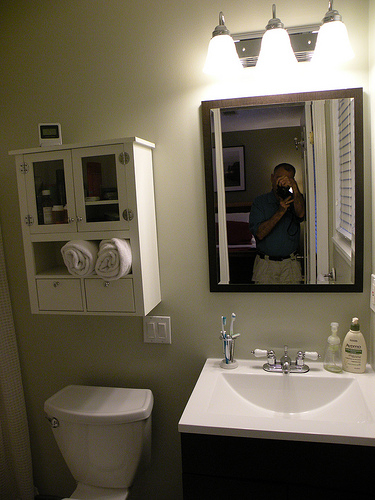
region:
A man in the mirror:
[248, 166, 304, 284]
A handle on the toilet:
[45, 416, 57, 425]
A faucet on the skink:
[254, 342, 318, 374]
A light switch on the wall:
[145, 316, 170, 341]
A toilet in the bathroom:
[45, 370, 152, 498]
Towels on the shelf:
[62, 237, 131, 275]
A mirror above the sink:
[208, 98, 355, 288]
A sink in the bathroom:
[222, 346, 353, 418]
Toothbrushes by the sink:
[218, 311, 238, 360]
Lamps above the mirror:
[208, 13, 350, 65]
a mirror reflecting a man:
[200, 88, 362, 290]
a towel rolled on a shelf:
[95, 237, 132, 282]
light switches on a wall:
[142, 313, 169, 346]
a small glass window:
[80, 155, 121, 223]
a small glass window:
[32, 157, 70, 225]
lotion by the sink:
[342, 316, 366, 372]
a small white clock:
[39, 121, 62, 146]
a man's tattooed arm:
[257, 196, 291, 240]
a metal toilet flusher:
[44, 413, 59, 428]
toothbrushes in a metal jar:
[218, 312, 239, 368]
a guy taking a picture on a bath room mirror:
[244, 148, 312, 292]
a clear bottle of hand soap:
[324, 310, 344, 378]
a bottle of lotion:
[341, 315, 367, 377]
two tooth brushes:
[214, 302, 249, 338]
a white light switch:
[139, 314, 175, 346]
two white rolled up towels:
[56, 234, 142, 283]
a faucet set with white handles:
[250, 337, 319, 378]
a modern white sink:
[176, 332, 373, 465]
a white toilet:
[32, 373, 146, 499]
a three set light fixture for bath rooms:
[193, 7, 369, 82]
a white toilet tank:
[43, 382, 154, 487]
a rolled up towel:
[92, 237, 132, 279]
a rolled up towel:
[59, 240, 97, 275]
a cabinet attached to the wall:
[9, 136, 162, 315]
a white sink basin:
[220, 369, 353, 412]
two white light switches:
[141, 316, 172, 342]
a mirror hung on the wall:
[199, 87, 365, 291]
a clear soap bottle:
[321, 319, 345, 373]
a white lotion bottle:
[339, 316, 366, 372]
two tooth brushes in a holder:
[218, 309, 237, 363]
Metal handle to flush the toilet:
[42, 411, 58, 429]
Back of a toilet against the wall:
[41, 379, 154, 488]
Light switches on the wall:
[140, 314, 171, 346]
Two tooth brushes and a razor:
[220, 311, 240, 368]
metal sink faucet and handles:
[249, 342, 319, 378]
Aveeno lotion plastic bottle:
[340, 315, 367, 373]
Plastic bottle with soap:
[320, 317, 345, 373]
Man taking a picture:
[248, 160, 309, 283]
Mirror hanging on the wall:
[193, 85, 368, 292]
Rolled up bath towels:
[58, 235, 131, 280]